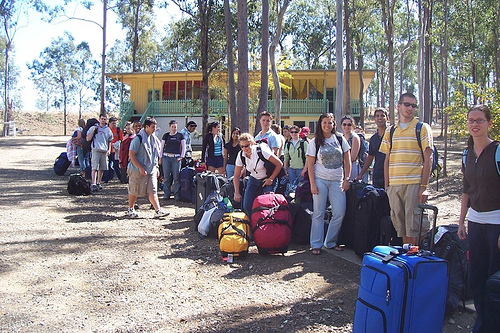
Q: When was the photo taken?
A: Morning.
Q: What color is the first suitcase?
A: Blue.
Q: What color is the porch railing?
A: Green.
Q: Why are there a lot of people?
A: Waiting.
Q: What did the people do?
A: Camp.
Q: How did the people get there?
A: Bus.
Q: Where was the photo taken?
A: At campgrounds.